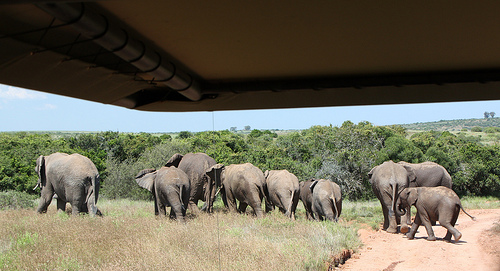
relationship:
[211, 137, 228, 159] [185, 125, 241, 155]
leaf on plant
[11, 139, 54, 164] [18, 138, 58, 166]
leaf on plant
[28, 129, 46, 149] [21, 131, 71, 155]
leaf on plant